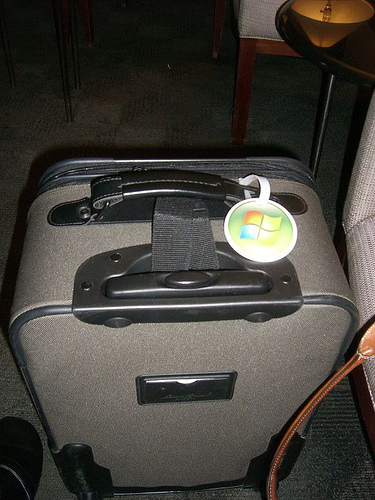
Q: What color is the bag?
A: Black and grey.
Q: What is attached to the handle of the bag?
A: A tag.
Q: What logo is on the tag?
A: Microsoft.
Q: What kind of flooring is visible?
A: Carpet.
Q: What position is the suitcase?
A: Standing.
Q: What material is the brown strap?
A: Leather.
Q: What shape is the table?
A: Round.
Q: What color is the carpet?
A: Light blue.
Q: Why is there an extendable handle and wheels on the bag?
A: To transport easily.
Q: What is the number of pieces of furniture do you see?
A: 4.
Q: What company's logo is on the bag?
A: Microsoft Windows.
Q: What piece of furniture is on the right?
A: Couch.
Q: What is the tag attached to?
A: Luggage.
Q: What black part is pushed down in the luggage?
A: Pull handle.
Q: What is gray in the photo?
A: A piece of luggage.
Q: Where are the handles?
A: On top.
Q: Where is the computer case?
A: The floor.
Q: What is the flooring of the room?
A: Carpet.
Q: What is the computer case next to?
A: The sofa.